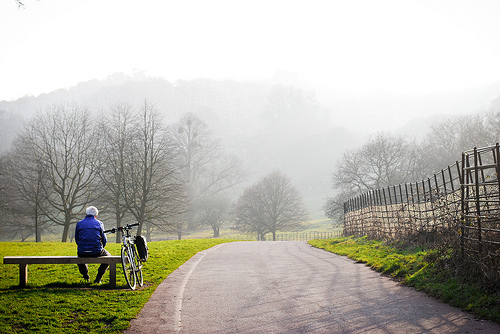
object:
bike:
[102, 218, 144, 292]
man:
[75, 204, 112, 282]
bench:
[0, 255, 135, 289]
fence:
[244, 142, 498, 283]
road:
[128, 230, 500, 333]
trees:
[0, 108, 499, 240]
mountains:
[0, 83, 498, 242]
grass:
[0, 240, 246, 333]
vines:
[376, 194, 492, 273]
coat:
[75, 214, 109, 258]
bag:
[131, 233, 149, 261]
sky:
[0, 0, 500, 141]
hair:
[85, 205, 100, 218]